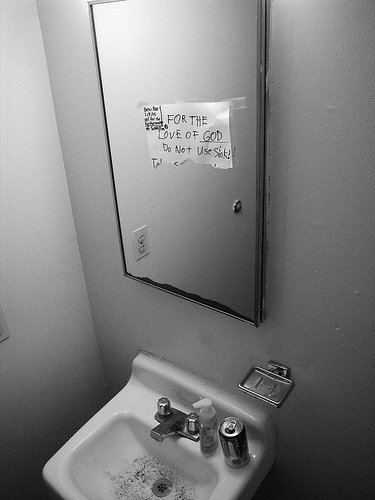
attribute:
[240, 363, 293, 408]
soap dish — hangin, silver, empty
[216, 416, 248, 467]
can — open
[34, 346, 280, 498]
sink — white, dirty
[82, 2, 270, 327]
mirror — hanging, large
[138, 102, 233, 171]
note — hanging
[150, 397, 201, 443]
faucet — metallic, older, silver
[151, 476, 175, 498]
drain — silver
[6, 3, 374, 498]
bathroom — large